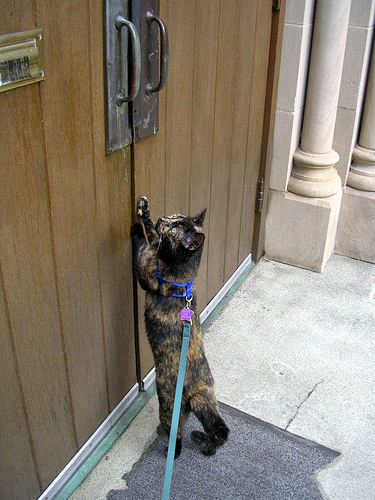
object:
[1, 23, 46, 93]
slot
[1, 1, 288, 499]
door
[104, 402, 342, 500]
mat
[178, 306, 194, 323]
tag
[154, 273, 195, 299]
harness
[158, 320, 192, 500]
leash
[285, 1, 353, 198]
pillar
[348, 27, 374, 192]
cloumn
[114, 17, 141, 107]
handle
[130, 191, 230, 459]
cat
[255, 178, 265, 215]
hinge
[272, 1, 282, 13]
hinge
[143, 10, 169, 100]
handle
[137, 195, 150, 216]
paw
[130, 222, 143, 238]
paw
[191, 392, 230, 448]
tail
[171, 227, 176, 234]
eye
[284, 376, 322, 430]
crack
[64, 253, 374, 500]
concrete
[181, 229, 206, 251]
ear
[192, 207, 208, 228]
ear